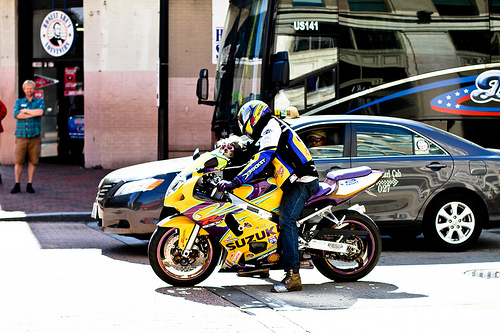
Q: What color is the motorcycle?
A: Yellow.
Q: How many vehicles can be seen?
A: 3.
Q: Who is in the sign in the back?
A: Abraham Lincoln.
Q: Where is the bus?
A: In the back.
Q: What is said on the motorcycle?
A: Suzuki.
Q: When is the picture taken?
A: Daytime.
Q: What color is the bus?
A: Black.